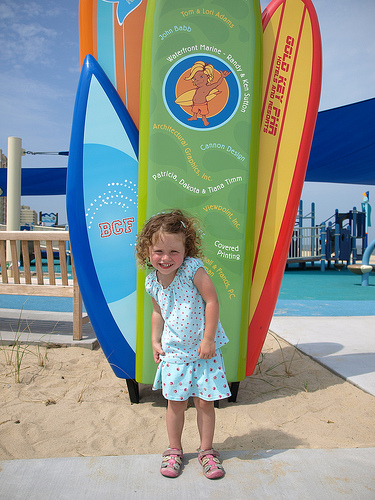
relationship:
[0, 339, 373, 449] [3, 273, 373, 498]
sand on ground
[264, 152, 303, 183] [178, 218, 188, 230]
ground has clip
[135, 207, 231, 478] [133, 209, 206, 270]
child has clip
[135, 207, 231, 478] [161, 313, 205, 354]
child wears outfit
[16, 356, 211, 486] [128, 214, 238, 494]
sand behind girl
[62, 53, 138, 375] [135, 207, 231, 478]
surfboard behind child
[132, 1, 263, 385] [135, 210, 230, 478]
surfboard behind girl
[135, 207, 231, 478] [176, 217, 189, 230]
child has barrette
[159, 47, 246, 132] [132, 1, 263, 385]
picture on surfboard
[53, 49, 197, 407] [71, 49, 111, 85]
blue surfboard has tip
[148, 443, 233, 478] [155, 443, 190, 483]
croc sandals on feet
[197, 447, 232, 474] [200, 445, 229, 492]
sandals on feet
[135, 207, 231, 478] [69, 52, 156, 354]
child standing in front of surfboard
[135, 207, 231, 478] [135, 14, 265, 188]
child standing in front of surfboard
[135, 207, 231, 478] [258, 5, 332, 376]
child standing in front of surfboard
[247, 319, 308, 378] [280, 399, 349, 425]
plant growing out of sand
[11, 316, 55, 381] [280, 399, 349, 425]
plant growing out of sand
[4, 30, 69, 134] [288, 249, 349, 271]
skies over beach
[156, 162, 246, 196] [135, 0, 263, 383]
lettering on sign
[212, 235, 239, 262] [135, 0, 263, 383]
lettering on sign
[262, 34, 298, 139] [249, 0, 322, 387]
red lettering on sign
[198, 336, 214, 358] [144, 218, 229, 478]
hand on girl